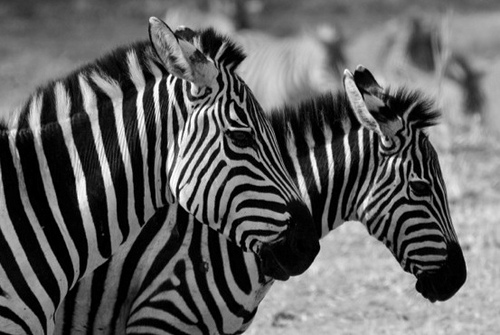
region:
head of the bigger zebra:
[140, 16, 322, 277]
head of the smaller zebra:
[337, 60, 471, 305]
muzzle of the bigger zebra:
[256, 202, 323, 284]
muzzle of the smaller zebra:
[418, 246, 467, 298]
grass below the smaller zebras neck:
[318, 267, 390, 334]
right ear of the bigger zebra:
[148, 16, 218, 88]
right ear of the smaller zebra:
[340, 69, 402, 149]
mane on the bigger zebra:
[13, 45, 155, 118]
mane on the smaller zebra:
[276, 96, 348, 137]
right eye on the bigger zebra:
[223, 122, 260, 151]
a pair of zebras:
[0, 15, 467, 332]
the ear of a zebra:
[146, 15, 221, 93]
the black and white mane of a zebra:
[2, 23, 248, 133]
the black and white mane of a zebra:
[264, 83, 444, 155]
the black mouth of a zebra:
[253, 196, 322, 282]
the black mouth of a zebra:
[416, 239, 471, 300]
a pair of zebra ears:
[335, 60, 400, 157]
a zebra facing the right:
[1, 15, 322, 333]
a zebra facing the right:
[52, 63, 467, 333]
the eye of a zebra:
[224, 125, 256, 150]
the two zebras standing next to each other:
[89, 60, 481, 313]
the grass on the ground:
[330, 282, 365, 321]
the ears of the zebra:
[146, 14, 196, 81]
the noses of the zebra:
[251, 207, 461, 327]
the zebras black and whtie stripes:
[49, 140, 136, 232]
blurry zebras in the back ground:
[281, 18, 444, 60]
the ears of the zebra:
[264, 21, 469, 155]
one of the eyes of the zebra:
[404, 175, 436, 197]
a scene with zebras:
[44, 16, 496, 310]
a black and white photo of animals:
[2, 4, 439, 310]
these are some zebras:
[35, 40, 457, 333]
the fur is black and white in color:
[62, 120, 160, 250]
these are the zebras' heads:
[143, 27, 485, 298]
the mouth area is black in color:
[273, 238, 319, 263]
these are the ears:
[340, 53, 410, 139]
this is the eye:
[228, 125, 261, 142]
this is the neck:
[16, 120, 168, 252]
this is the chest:
[218, 280, 249, 315]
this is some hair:
[303, 107, 343, 148]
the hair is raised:
[303, 109, 333, 146]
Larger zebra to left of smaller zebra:
[1, 15, 322, 334]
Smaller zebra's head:
[318, 54, 470, 305]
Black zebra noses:
[252, 193, 472, 305]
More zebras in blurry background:
[162, 1, 497, 148]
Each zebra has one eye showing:
[220, 123, 437, 203]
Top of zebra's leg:
[121, 280, 219, 333]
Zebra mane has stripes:
[12, 23, 249, 126]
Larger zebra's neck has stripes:
[6, 85, 171, 276]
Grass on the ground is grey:
[248, 201, 498, 333]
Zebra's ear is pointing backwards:
[341, 63, 394, 153]